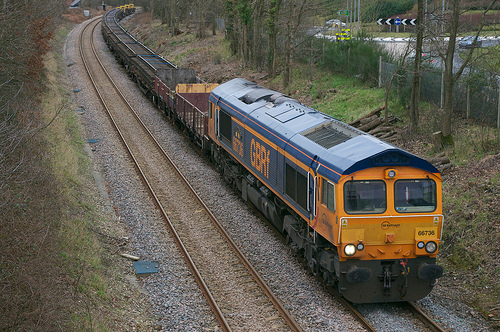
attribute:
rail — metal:
[132, 169, 262, 301]